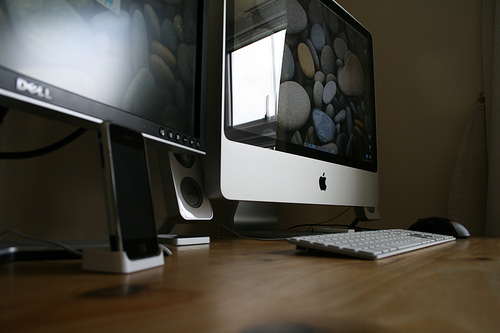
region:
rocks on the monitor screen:
[280, 63, 349, 133]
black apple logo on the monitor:
[313, 170, 332, 198]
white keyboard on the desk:
[297, 225, 456, 258]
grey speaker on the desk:
[158, 143, 217, 254]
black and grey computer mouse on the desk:
[409, 212, 476, 237]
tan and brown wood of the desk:
[173, 261, 369, 318]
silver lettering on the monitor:
[5, 70, 67, 114]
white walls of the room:
[386, 13, 448, 115]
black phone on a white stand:
[91, 123, 170, 278]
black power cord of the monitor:
[1, 123, 88, 157]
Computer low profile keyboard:
[282, 226, 457, 261]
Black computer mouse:
[405, 215, 470, 236]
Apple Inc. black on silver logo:
[315, 170, 325, 191]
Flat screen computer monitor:
[196, 0, 381, 240]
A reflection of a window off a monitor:
[221, 0, 286, 150]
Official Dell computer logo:
[13, 75, 54, 102]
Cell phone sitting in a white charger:
[78, 119, 166, 276]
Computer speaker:
[153, 147, 215, 248]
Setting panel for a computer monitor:
[157, 127, 208, 157]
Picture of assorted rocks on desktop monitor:
[276, 0, 361, 156]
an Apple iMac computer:
[199, 0, 381, 239]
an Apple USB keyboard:
[288, 225, 455, 262]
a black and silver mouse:
[410, 215, 470, 238]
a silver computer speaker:
[158, 144, 214, 246]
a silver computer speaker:
[347, 205, 380, 229]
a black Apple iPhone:
[95, 118, 160, 262]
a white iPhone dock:
[76, 241, 165, 274]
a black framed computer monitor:
[0, 0, 214, 162]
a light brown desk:
[3, 234, 497, 330]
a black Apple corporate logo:
[317, 171, 329, 192]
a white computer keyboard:
[323, 229, 455, 285]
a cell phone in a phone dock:
[85, 128, 156, 279]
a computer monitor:
[225, 24, 391, 221]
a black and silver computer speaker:
[161, 135, 221, 257]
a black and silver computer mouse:
[398, 215, 472, 242]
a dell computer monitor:
[1, 26, 209, 144]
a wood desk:
[167, 198, 464, 330]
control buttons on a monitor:
[146, 119, 209, 151]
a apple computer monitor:
[215, 93, 401, 234]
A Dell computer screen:
[0, 2, 207, 156]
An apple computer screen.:
[221, 2, 378, 208]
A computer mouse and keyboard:
[289, 214, 464, 259]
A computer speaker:
[162, 143, 215, 221]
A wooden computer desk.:
[4, 243, 498, 320]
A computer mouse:
[413, 213, 474, 236]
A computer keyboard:
[288, 223, 458, 263]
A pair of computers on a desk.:
[1, 0, 421, 209]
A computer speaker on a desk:
[342, 203, 389, 220]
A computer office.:
[0, 0, 497, 331]